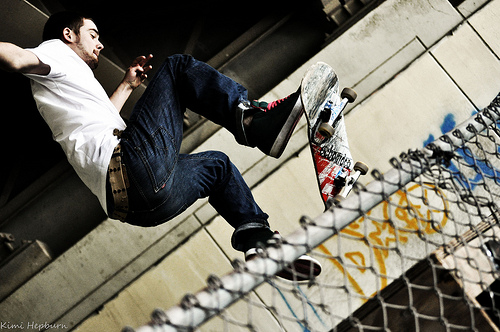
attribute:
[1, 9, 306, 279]
male — young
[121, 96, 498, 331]
fence — chain link, grey 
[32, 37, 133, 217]
shirt — white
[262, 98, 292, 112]
shoelaces — pink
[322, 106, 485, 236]
pole — metal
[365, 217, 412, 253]
painted star — yellow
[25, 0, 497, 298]
wall — tan color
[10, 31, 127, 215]
t-shirt — white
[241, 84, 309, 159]
shoe — black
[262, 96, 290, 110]
lace — red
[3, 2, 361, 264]
boy — skating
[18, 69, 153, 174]
shirt — white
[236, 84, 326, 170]
shoe — black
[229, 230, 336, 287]
shoe — black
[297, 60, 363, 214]
skateboard — white, red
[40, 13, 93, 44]
hair — black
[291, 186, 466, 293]
graffiti — yellow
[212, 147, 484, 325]
wall — concrete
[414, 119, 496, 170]
graffiti — blue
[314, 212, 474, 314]
fence — grey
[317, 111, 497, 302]
letters — brown, blue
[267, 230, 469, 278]
fence — chain link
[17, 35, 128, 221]
shirt — white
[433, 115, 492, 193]
graffiti — blue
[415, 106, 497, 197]
graffiti — blue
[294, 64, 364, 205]
skate board — white, red, black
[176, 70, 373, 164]
shoe — black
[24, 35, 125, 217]
shirt — white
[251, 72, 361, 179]
shoe — black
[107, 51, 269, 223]
pants — blue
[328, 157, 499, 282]
graffiti — yellow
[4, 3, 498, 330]
wall — brown, concrete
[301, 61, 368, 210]
skateboard — white